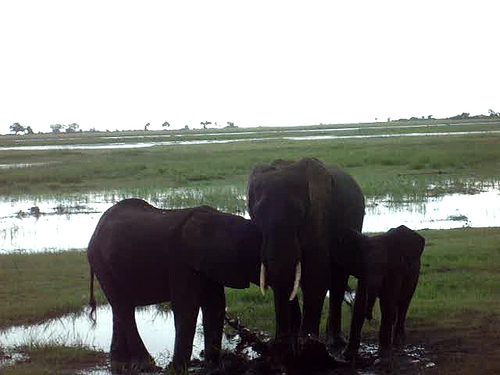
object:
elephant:
[243, 154, 366, 358]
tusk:
[288, 261, 303, 304]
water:
[16, 213, 60, 237]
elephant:
[80, 194, 262, 374]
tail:
[86, 266, 100, 330]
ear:
[180, 211, 252, 289]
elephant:
[337, 224, 429, 361]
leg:
[299, 277, 327, 340]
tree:
[10, 123, 26, 136]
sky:
[0, 0, 500, 134]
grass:
[425, 260, 479, 308]